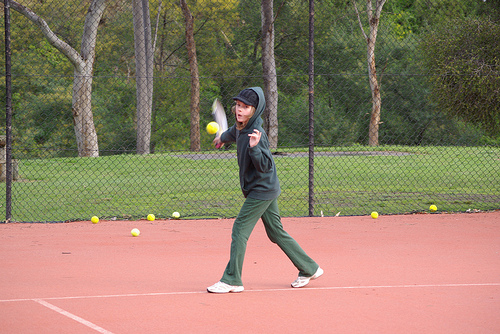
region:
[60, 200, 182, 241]
a few balls on the ground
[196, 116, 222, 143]
a yellow tennis ball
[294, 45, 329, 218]
a black metal pole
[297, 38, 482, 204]
a black chain link fence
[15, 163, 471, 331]
a red tennis court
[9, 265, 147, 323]
white lines on a court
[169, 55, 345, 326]
a young girl playing tennis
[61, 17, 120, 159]
a slightly curved tree trunk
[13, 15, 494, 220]
a park like setting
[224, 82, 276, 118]
a black hat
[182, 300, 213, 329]
part of a court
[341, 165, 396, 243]
part of a fence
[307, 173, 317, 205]
part of a metal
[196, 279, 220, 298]
edge of a shoe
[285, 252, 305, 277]
part of a trouser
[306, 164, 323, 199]
part of a metal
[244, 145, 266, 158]
part of a sleeve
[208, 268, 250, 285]
edge of a trouser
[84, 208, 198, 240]
Tennis balls lying on the ground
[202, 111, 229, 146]
Tennis ball in play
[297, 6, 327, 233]
Vertical support posts for chain-link fence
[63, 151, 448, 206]
Large grassy field in the background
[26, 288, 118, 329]
Lines painted on a tennis court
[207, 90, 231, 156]
Tennis racket swung by tennis player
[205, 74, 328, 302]
Tennis player wearing a hoodie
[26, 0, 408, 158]
Row of trees in the background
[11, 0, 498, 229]
Chain-link enclosure for tennis court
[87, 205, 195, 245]
Tennis balls out of bounds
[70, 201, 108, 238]
the ball is yellow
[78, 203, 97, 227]
the ball is yellow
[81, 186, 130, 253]
the ball is yellow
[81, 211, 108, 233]
the ball is yellow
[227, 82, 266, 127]
the head of a woman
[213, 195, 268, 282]
the leg of a woman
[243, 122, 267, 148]
the hand of a woman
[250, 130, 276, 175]
the arm of a woman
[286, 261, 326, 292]
a white tennis shoe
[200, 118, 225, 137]
a tennis ball in the air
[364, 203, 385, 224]
a tennis ball on the ground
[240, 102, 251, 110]
the eye of a woman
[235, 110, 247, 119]
the mouth of a woman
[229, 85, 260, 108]
a black baseball cap